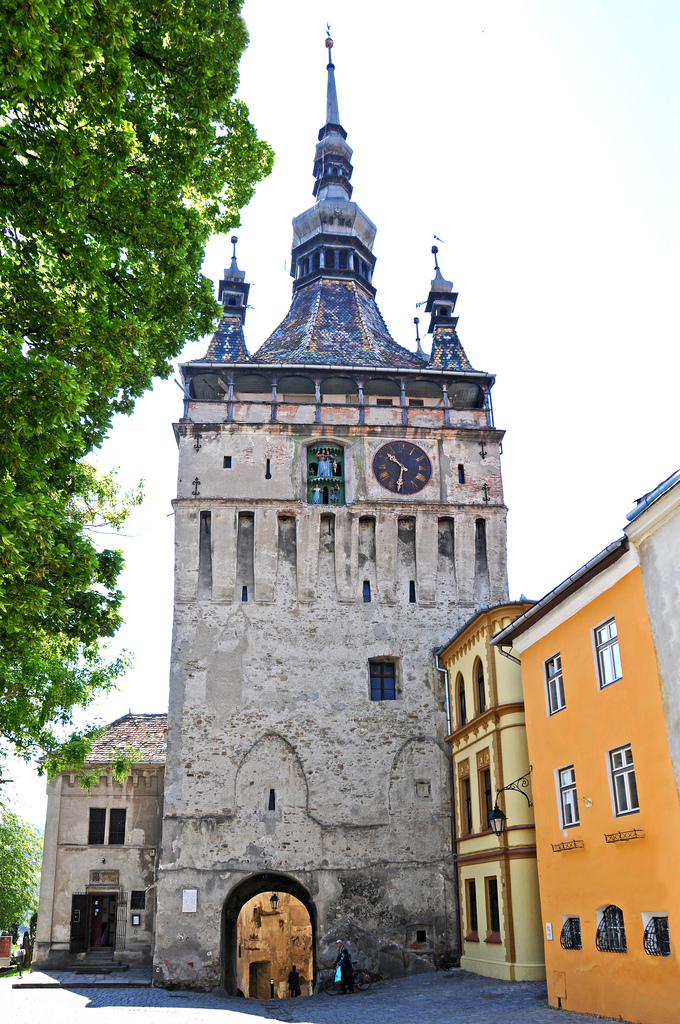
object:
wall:
[235, 892, 311, 1001]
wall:
[159, 518, 433, 871]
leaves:
[0, 2, 274, 750]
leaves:
[35, 592, 82, 668]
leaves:
[4, 703, 132, 783]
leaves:
[0, 266, 219, 381]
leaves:
[38, 142, 98, 252]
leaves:
[30, 43, 167, 142]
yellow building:
[520, 547, 680, 1024]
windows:
[607, 740, 643, 816]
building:
[437, 603, 541, 984]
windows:
[454, 654, 499, 945]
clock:
[372, 440, 431, 497]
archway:
[219, 868, 320, 1000]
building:
[432, 536, 680, 994]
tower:
[152, 24, 506, 994]